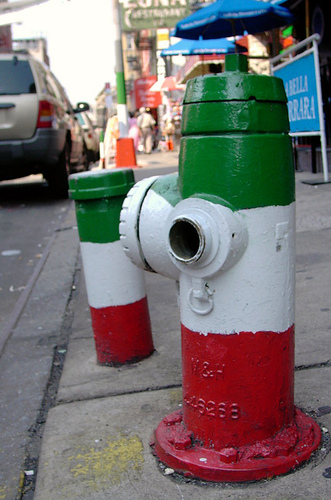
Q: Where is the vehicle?
A: On the road.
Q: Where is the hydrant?
A: On the road.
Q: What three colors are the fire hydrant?
A: Red white and green.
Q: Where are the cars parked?
A: On a city street.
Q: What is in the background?
A: Blue and silver store sign.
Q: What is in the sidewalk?
A: Red white and green fire hydrant.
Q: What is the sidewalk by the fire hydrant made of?
A: Cement.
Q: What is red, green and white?
A: Fire hydrant.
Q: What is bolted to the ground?
A: Fire hydrant.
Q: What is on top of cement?
A: Fire hydrant.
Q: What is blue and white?
A: Sign.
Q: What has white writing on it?
A: Two umbrellas.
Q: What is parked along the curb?
A: A car.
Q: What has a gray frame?
A: The blue sign.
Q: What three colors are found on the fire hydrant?
A: Red, white and green.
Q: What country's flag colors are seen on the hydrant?
A: Mexico.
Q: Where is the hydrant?
A: Sidewalk.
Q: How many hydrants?
A: 1.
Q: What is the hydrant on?
A: Sidewalk.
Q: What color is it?
A: Green, white and red.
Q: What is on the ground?
A: Hydrant.